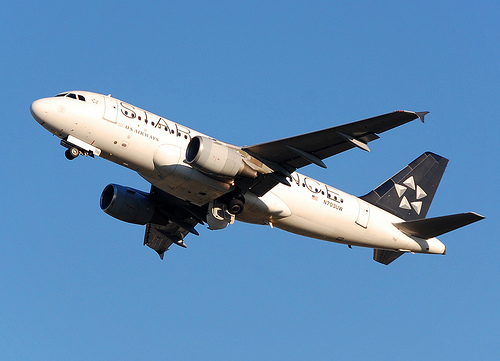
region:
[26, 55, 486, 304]
Flight is on the sky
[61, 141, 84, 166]
Front wheel of the flight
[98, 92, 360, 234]
Front side wings of the flight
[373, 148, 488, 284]
Back side wings of the flight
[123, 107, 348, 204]
Lot of windows in the flight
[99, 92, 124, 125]
Front side door of the flight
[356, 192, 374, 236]
Back side door of the flight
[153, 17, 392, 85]
A blue color clear sky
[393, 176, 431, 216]
Logo of the flight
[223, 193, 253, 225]
Back side wheel of the flight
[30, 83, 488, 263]
White large plane flying in blue sky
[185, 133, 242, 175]
Jet engine below wing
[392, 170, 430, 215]
White logo on tail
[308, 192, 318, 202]
American flag on plane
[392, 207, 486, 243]
Horizontal stabilizer is blue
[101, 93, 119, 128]
White door next to small window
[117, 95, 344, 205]
Large logo across plane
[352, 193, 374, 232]
White door near tail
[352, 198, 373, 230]
White door near horizontal stabilizer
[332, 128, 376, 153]
Gray slat under wing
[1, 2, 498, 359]
THE CLEAR SKY IS VERY BLUE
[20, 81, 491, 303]
THE PLANE IS IN THE AIR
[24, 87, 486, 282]
THIS IS A PLANE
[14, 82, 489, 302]
THE PLAIN IS IN THE SKY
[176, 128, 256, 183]
THIS IS AN ENGINE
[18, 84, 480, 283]
THE PLANE IS FLYING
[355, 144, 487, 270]
THIS IS THE TAIL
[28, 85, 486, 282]
THE PLANE IS WHITE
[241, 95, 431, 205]
THIS IS A WING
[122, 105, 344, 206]
THE PLANE HAS MANY WINDOWS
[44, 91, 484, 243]
this is a jet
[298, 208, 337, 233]
the jet is white in color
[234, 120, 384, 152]
this is the wing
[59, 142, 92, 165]
this is the wheel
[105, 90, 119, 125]
this is the door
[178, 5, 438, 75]
this is the sky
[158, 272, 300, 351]
the sky is blue in color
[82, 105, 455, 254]
the jet is on air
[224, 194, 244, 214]
the wheel is black in color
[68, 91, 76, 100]
this is the window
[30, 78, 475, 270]
this is a plane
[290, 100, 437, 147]
this is the wing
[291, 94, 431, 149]
the wing is sharp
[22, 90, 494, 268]
the plane is big in size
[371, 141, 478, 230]
this is the tail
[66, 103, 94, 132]
the plane in white in color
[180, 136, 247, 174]
this is a propeller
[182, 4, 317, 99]
the sky is blue in color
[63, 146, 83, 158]
this is the wheel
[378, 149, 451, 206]
the wheel is black in color